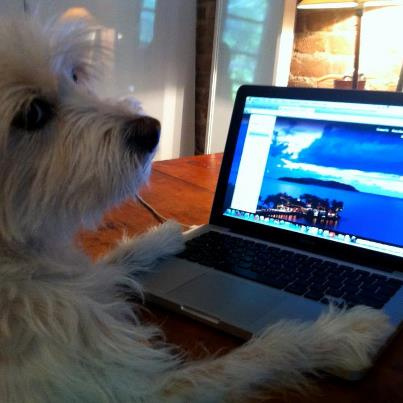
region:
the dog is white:
[3, 38, 108, 347]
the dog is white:
[25, 86, 175, 363]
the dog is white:
[33, 210, 183, 385]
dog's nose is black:
[117, 119, 175, 161]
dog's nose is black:
[87, 99, 178, 189]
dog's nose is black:
[104, 109, 181, 148]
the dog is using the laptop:
[52, 56, 390, 349]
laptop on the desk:
[174, 106, 395, 391]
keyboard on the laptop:
[190, 233, 379, 314]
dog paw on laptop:
[286, 296, 375, 376]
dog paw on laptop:
[135, 219, 191, 263]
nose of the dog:
[122, 115, 166, 169]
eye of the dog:
[15, 97, 50, 135]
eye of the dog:
[67, 68, 91, 96]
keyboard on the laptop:
[231, 263, 263, 284]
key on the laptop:
[200, 242, 212, 255]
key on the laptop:
[305, 273, 325, 289]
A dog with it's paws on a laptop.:
[0, 1, 401, 400]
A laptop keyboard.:
[178, 227, 400, 307]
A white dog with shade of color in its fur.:
[0, 7, 391, 401]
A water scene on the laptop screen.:
[223, 98, 401, 244]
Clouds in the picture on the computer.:
[269, 123, 400, 174]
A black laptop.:
[108, 81, 396, 365]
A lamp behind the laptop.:
[294, 0, 401, 86]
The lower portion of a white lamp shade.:
[292, 0, 395, 8]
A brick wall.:
[284, 3, 397, 94]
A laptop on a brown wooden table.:
[26, 80, 399, 395]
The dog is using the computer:
[0, 12, 381, 384]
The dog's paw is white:
[260, 275, 398, 400]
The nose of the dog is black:
[116, 110, 165, 158]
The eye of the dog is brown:
[7, 91, 61, 134]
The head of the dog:
[0, 12, 170, 244]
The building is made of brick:
[291, 14, 356, 79]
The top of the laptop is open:
[178, 81, 397, 269]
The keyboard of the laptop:
[170, 228, 397, 325]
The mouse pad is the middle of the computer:
[163, 265, 293, 331]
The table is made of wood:
[118, 157, 216, 226]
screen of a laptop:
[222, 80, 402, 265]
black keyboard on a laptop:
[174, 231, 399, 319]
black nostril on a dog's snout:
[117, 110, 167, 153]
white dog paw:
[109, 219, 201, 275]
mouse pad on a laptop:
[166, 265, 278, 324]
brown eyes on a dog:
[9, 60, 90, 134]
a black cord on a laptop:
[138, 190, 170, 237]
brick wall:
[293, 4, 399, 104]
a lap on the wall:
[295, 1, 402, 89]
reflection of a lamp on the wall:
[50, 7, 113, 31]